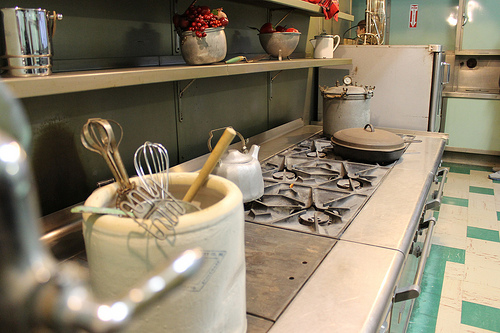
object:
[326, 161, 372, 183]
stove top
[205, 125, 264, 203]
tea kettle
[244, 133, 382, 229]
iron burners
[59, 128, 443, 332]
counter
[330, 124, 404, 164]
pan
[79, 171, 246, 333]
ceramic jar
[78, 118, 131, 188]
utensil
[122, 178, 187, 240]
utensil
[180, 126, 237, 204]
utensil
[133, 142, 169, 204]
utensil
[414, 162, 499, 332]
floor tiles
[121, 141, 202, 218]
potato masher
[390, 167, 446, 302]
handles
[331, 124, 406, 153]
lid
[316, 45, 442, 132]
refrigerator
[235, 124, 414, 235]
burner